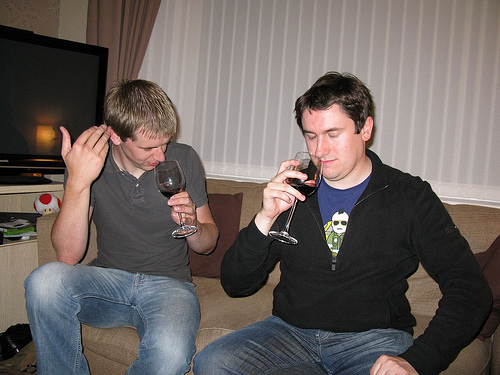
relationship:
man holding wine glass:
[192, 69, 492, 374] [268, 151, 324, 245]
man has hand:
[192, 69, 492, 374] [260, 158, 308, 216]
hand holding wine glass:
[260, 158, 308, 216] [268, 151, 324, 245]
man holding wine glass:
[23, 78, 220, 374] [154, 160, 199, 241]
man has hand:
[23, 78, 220, 374] [166, 188, 197, 226]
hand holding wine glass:
[166, 188, 197, 226] [154, 160, 199, 241]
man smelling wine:
[192, 69, 492, 374] [289, 175, 317, 197]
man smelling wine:
[23, 78, 220, 374] [159, 186, 181, 199]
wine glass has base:
[268, 151, 324, 245] [267, 229, 299, 246]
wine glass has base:
[154, 160, 199, 241] [171, 225, 199, 240]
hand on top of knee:
[367, 350, 417, 374] [338, 372, 418, 374]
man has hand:
[23, 78, 220, 374] [57, 122, 110, 183]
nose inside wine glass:
[314, 136, 331, 160] [268, 151, 324, 245]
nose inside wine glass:
[155, 145, 168, 163] [154, 160, 199, 241]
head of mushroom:
[39, 205, 55, 214] [32, 192, 62, 216]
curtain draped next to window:
[85, 0, 164, 105] [133, 1, 499, 206]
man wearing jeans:
[192, 69, 492, 374] [191, 313, 412, 374]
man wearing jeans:
[23, 78, 220, 374] [22, 260, 202, 374]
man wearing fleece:
[192, 69, 492, 374] [219, 148, 493, 374]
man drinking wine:
[192, 69, 492, 374] [289, 175, 317, 197]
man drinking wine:
[23, 78, 220, 374] [159, 186, 181, 199]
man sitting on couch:
[192, 69, 492, 374] [35, 177, 498, 374]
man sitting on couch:
[23, 78, 220, 374] [35, 177, 498, 374]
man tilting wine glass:
[192, 69, 492, 374] [268, 151, 324, 245]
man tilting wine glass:
[23, 78, 220, 374] [154, 160, 199, 241]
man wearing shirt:
[192, 69, 492, 374] [314, 172, 370, 273]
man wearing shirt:
[23, 78, 220, 374] [64, 137, 208, 285]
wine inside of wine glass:
[289, 175, 317, 197] [268, 151, 324, 245]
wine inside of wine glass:
[159, 186, 181, 199] [154, 160, 199, 241]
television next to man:
[1, 26, 110, 183] [23, 78, 220, 374]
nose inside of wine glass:
[314, 136, 331, 160] [268, 151, 324, 245]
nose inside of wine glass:
[155, 145, 168, 163] [154, 160, 199, 241]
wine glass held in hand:
[268, 151, 324, 245] [260, 158, 308, 216]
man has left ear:
[192, 69, 492, 374] [360, 113, 375, 144]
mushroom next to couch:
[32, 192, 62, 216] [35, 177, 498, 374]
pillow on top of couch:
[185, 189, 242, 277] [35, 177, 498, 374]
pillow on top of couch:
[472, 231, 499, 342] [35, 177, 498, 374]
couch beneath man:
[35, 177, 498, 374] [217, 69, 492, 375]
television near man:
[1, 26, 110, 183] [217, 69, 492, 375]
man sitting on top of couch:
[192, 69, 492, 374] [35, 177, 498, 374]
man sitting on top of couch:
[23, 78, 220, 374] [35, 177, 498, 374]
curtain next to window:
[85, 0, 164, 105] [133, 1, 499, 206]